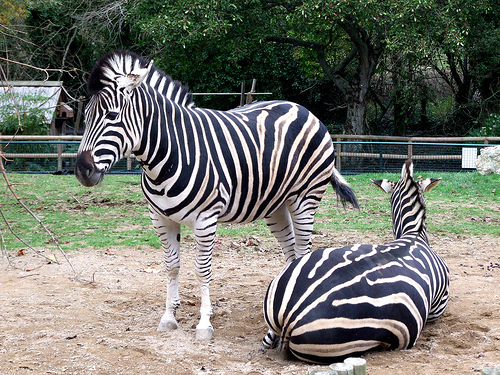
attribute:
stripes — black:
[77, 54, 462, 374]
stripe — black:
[251, 102, 311, 219]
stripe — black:
[229, 126, 245, 160]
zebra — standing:
[54, 37, 323, 352]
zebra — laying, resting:
[262, 162, 451, 364]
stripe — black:
[293, 300, 421, 347]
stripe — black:
[205, 111, 245, 208]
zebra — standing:
[63, 56, 338, 357]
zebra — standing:
[74, 47, 360, 341]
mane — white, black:
[88, 47, 197, 106]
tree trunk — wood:
[323, 32, 378, 168]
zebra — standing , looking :
[72, 56, 384, 254]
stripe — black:
[231, 125, 235, 142]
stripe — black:
[225, 119, 279, 234]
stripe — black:
[366, 267, 406, 283]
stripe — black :
[401, 196, 420, 217]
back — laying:
[301, 236, 443, 289]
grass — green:
[50, 198, 129, 252]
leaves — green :
[389, 16, 483, 76]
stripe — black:
[256, 120, 328, 186]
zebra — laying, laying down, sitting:
[255, 157, 452, 373]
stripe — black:
[194, 241, 215, 249]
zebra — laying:
[269, 167, 471, 360]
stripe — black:
[344, 239, 384, 269]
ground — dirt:
[8, 221, 482, 361]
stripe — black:
[201, 134, 269, 211]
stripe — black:
[398, 213, 415, 223]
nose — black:
[67, 155, 109, 195]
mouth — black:
[84, 162, 108, 189]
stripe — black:
[327, 293, 442, 347]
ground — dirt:
[9, 225, 495, 371]